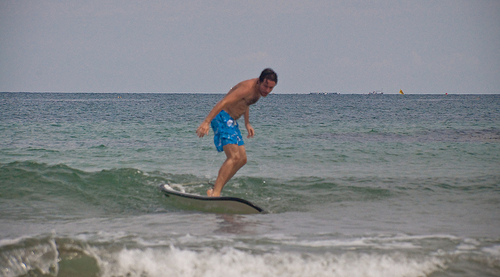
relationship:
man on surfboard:
[194, 65, 288, 194] [159, 177, 268, 218]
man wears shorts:
[194, 65, 288, 194] [209, 113, 251, 150]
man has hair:
[194, 65, 288, 194] [260, 69, 281, 83]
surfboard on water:
[159, 177, 268, 218] [381, 148, 448, 176]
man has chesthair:
[194, 65, 288, 194] [244, 97, 258, 107]